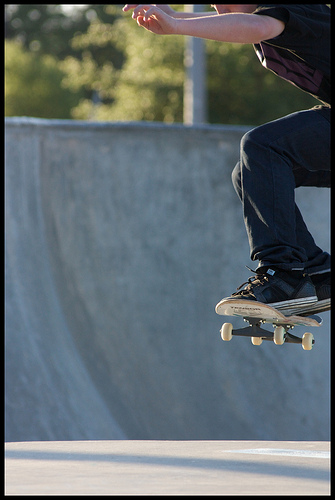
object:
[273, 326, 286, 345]
wheels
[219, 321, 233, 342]
wheels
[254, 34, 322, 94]
logo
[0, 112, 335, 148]
ground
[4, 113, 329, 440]
ramp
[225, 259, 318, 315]
shoe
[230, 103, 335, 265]
jeans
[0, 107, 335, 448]
fence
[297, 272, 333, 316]
skate shoe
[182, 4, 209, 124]
metal pole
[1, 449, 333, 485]
shadow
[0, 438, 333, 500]
pavement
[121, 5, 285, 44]
arm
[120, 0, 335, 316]
boy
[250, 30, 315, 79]
top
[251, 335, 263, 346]
wheel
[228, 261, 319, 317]
black sneakers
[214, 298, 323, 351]
skate board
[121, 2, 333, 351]
person/skateboard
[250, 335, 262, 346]
wheels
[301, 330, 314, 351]
wheels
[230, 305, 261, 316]
black logo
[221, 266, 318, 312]
feet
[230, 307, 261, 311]
writing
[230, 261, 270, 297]
shoe strings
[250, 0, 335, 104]
tee shirt